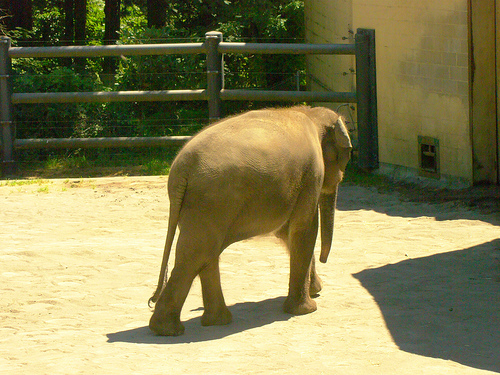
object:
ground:
[0, 164, 500, 375]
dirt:
[0, 164, 500, 375]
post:
[205, 30, 224, 126]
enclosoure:
[1, 26, 500, 375]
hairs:
[182, 101, 348, 151]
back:
[193, 105, 306, 159]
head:
[291, 105, 354, 264]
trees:
[0, 0, 55, 47]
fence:
[0, 26, 380, 176]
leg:
[198, 246, 234, 327]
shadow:
[350, 236, 500, 373]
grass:
[340, 153, 397, 193]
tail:
[147, 150, 194, 309]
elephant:
[147, 105, 353, 336]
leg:
[274, 219, 324, 297]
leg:
[148, 164, 247, 336]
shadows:
[334, 168, 500, 227]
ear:
[333, 115, 354, 181]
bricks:
[449, 66, 468, 82]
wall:
[303, 0, 496, 190]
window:
[417, 135, 441, 181]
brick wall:
[304, 0, 473, 187]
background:
[0, 0, 500, 200]